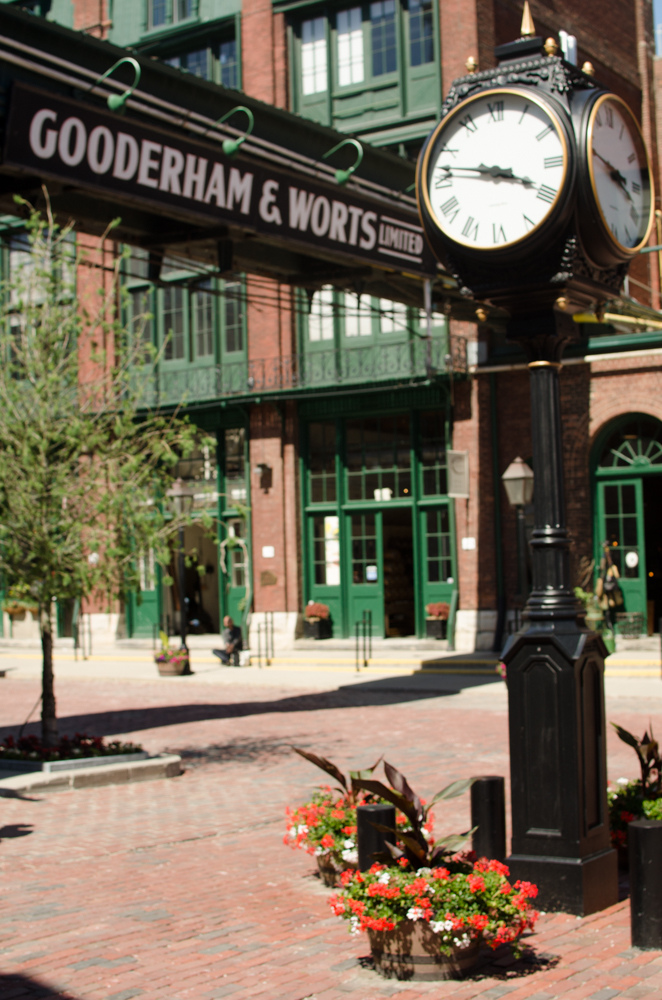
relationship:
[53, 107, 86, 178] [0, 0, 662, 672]
letter on background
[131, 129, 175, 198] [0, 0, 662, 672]
letter on a background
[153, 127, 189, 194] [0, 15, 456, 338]
letter on a sign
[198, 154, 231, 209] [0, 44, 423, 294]
letter on a sign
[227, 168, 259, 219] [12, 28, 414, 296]
letter on a sign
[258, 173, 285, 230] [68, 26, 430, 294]
letter on a sign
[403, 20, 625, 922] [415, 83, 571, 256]
clock with face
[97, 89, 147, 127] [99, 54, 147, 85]
light on pole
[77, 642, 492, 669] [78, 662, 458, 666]
stairs with edge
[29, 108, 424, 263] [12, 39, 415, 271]
sign on background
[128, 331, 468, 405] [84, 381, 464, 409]
railing on edge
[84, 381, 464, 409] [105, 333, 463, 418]
edge of balcony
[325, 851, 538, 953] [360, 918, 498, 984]
flowers in pot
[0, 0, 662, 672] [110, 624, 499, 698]
background hanging above street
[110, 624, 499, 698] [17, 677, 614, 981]
street in lot